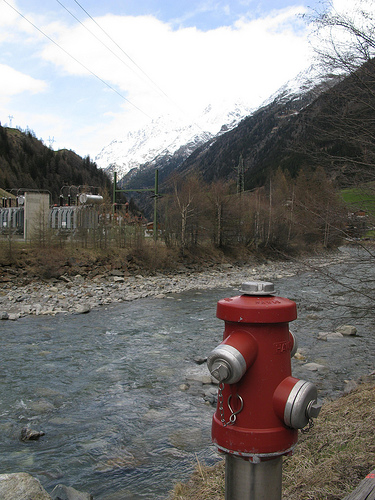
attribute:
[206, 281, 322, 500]
fire hydrant — red, silver, grey, metal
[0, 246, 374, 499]
creek — water, clear, flowing, running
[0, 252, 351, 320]
rocky area — the shore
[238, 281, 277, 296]
cap — grey, metal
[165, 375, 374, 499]
grass — brown, dry, dead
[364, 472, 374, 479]
marking — red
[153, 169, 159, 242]
post — green, metal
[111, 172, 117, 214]
post — green, metal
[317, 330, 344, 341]
rock — large, big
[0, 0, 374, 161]
sky — cloudy, blue, overhead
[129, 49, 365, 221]
mountain — snowy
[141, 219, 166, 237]
house — red, wooden, distant, white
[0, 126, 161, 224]
hillside — wooded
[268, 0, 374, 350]
tree — bare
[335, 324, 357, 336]
rock — big, large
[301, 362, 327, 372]
rock — big, large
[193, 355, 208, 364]
rock — big, large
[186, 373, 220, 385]
rock — big, large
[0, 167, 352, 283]
wooded area — dead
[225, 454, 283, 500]
post — grey, metal